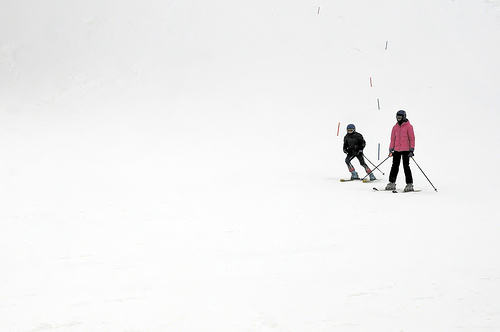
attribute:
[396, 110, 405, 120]
skully — white, black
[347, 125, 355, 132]
skully — white, black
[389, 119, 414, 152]
jacket — pink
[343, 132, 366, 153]
jacket — black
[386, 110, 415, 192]
person — skiiing, skiing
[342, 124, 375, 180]
person — skiing, bending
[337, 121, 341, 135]
pole — orange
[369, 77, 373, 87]
pole — orange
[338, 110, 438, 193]
two skiers — dressed, riding, skiing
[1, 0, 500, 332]
snow — white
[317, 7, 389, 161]
poles — colored